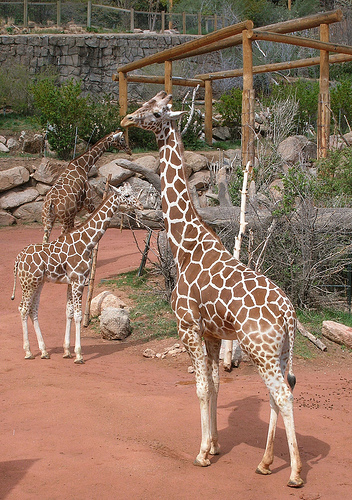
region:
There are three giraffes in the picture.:
[27, 102, 305, 472]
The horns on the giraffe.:
[156, 90, 177, 104]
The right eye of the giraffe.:
[150, 109, 169, 122]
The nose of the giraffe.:
[122, 112, 140, 123]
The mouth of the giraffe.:
[118, 118, 129, 128]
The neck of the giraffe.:
[151, 134, 206, 249]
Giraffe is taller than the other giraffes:
[113, 75, 324, 491]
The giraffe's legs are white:
[185, 379, 316, 486]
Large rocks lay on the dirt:
[78, 276, 134, 352]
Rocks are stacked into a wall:
[6, 144, 349, 238]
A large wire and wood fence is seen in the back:
[1, 1, 307, 46]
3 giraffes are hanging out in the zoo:
[22, 82, 316, 485]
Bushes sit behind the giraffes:
[18, 56, 349, 152]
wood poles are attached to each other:
[110, 9, 349, 180]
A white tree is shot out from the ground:
[226, 154, 255, 377]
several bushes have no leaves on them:
[222, 75, 348, 347]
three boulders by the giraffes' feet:
[88, 291, 129, 338]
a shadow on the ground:
[0, 457, 40, 498]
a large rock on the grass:
[319, 316, 350, 346]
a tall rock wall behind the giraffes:
[1, 32, 200, 110]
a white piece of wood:
[232, 160, 252, 258]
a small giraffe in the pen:
[10, 182, 142, 362]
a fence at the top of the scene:
[0, 0, 210, 39]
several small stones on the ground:
[141, 341, 185, 360]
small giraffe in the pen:
[10, 181, 141, 364]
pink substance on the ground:
[0, 224, 350, 498]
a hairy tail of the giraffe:
[287, 373, 295, 389]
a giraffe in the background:
[39, 129, 131, 243]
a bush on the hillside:
[17, 66, 118, 161]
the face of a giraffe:
[119, 89, 184, 133]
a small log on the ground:
[295, 319, 327, 353]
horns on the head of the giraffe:
[155, 91, 172, 103]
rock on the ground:
[98, 306, 133, 338]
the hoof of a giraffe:
[192, 457, 209, 466]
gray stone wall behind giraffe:
[1, 32, 237, 124]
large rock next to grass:
[98, 308, 132, 340]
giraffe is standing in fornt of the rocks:
[42, 128, 134, 240]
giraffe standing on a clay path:
[0, 224, 350, 498]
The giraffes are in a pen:
[6, 80, 331, 491]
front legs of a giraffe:
[178, 330, 238, 472]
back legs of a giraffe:
[252, 355, 305, 490]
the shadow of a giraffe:
[206, 386, 335, 489]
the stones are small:
[82, 282, 137, 348]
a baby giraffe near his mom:
[6, 82, 266, 416]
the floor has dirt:
[6, 357, 179, 489]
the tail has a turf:
[282, 312, 302, 395]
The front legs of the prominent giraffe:
[170, 325, 232, 469]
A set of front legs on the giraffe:
[175, 330, 238, 472]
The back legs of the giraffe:
[239, 338, 324, 491]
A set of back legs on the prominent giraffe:
[245, 334, 338, 487]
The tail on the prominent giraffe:
[283, 326, 303, 392]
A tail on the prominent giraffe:
[286, 326, 314, 390]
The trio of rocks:
[84, 287, 132, 344]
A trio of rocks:
[84, 288, 136, 347]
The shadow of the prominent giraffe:
[208, 373, 337, 478]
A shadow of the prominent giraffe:
[206, 383, 342, 487]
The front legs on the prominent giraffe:
[176, 332, 237, 475]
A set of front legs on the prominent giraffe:
[173, 327, 236, 476]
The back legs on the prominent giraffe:
[236, 332, 329, 491]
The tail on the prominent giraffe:
[277, 312, 311, 387]